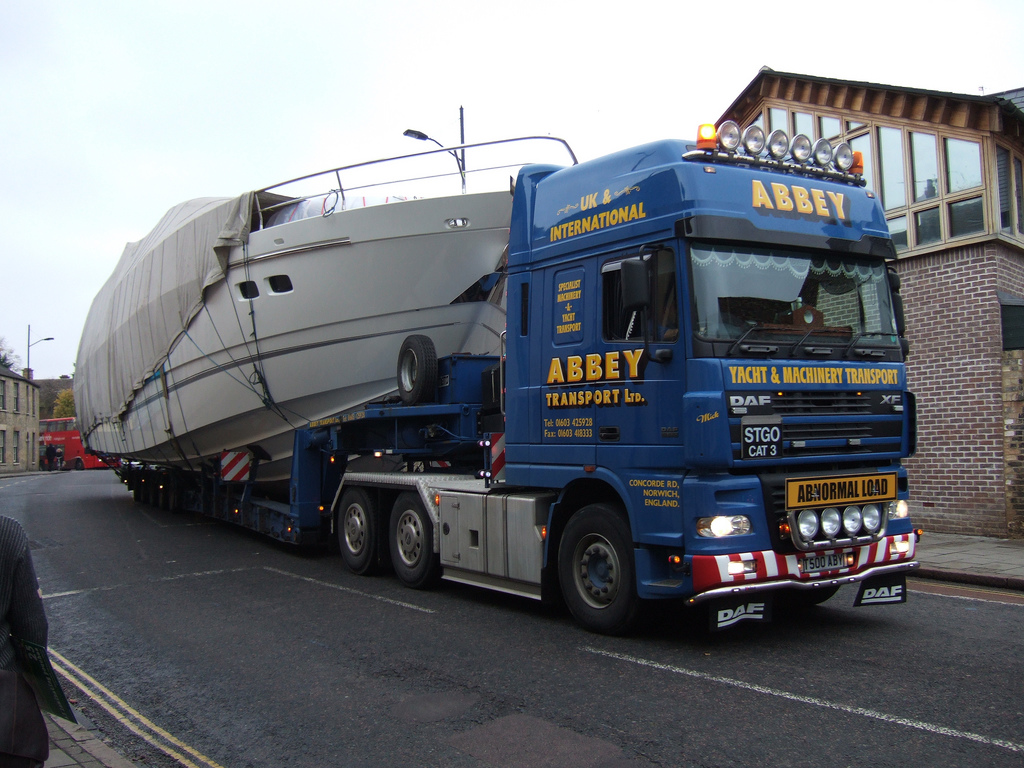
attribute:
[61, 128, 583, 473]
equipment — heavy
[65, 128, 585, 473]
boat — white, large cruiser , large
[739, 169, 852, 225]
name — moving company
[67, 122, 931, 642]
truck — large, blue, Abbey Transport Ltd